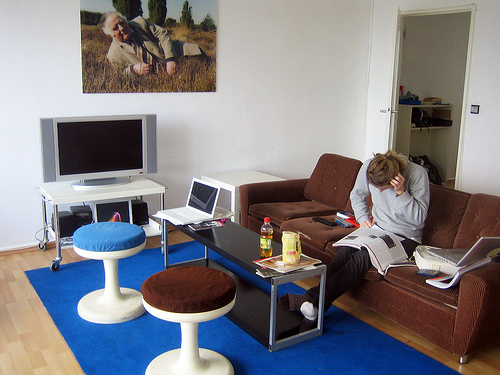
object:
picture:
[80, 0, 218, 93]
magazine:
[328, 220, 407, 273]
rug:
[21, 239, 458, 374]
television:
[35, 112, 159, 185]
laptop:
[156, 178, 221, 226]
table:
[157, 204, 329, 352]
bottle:
[258, 218, 273, 257]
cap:
[262, 217, 270, 223]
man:
[284, 147, 430, 321]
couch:
[237, 152, 497, 364]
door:
[384, 7, 401, 156]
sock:
[300, 301, 318, 323]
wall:
[0, 1, 366, 251]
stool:
[139, 261, 237, 375]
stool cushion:
[69, 219, 145, 256]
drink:
[258, 231, 269, 258]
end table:
[204, 168, 282, 187]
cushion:
[137, 265, 236, 313]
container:
[279, 230, 310, 265]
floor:
[0, 213, 499, 375]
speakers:
[53, 209, 78, 238]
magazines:
[253, 250, 322, 274]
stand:
[34, 178, 169, 272]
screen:
[59, 119, 146, 174]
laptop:
[423, 237, 498, 269]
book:
[423, 259, 489, 291]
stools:
[71, 221, 146, 325]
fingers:
[387, 179, 395, 186]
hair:
[364, 152, 406, 190]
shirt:
[346, 161, 430, 239]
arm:
[235, 176, 307, 222]